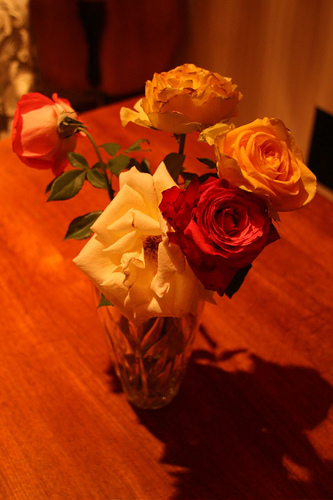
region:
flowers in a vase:
[21, 62, 284, 336]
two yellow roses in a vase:
[125, 53, 319, 217]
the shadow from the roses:
[203, 329, 327, 457]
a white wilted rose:
[109, 180, 211, 339]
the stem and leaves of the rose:
[61, 120, 130, 228]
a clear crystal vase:
[93, 303, 205, 412]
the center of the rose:
[136, 229, 174, 267]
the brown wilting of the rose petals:
[149, 72, 237, 122]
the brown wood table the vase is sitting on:
[23, 316, 161, 471]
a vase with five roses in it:
[27, 61, 309, 340]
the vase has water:
[106, 300, 197, 389]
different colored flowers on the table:
[16, 68, 270, 260]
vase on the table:
[90, 273, 219, 442]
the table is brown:
[32, 279, 302, 458]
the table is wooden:
[24, 279, 310, 450]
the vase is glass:
[89, 293, 196, 431]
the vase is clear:
[96, 287, 213, 459]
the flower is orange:
[231, 123, 272, 179]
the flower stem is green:
[60, 111, 108, 213]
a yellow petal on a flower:
[131, 62, 241, 141]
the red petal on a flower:
[162, 192, 251, 273]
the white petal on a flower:
[92, 223, 168, 280]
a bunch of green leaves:
[39, 159, 97, 206]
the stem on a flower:
[73, 131, 122, 182]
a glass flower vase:
[95, 284, 185, 419]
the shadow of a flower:
[195, 342, 323, 473]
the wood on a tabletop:
[13, 347, 100, 466]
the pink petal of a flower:
[23, 109, 60, 149]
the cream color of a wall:
[245, 51, 305, 114]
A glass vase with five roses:
[55, 83, 286, 418]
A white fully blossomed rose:
[71, 171, 191, 327]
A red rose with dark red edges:
[140, 166, 271, 289]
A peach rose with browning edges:
[195, 101, 326, 204]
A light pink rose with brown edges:
[103, 52, 247, 139]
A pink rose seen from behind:
[6, 65, 97, 182]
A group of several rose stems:
[67, 134, 214, 234]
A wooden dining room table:
[3, 105, 314, 492]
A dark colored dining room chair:
[264, 82, 331, 176]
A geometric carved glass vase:
[99, 302, 181, 416]